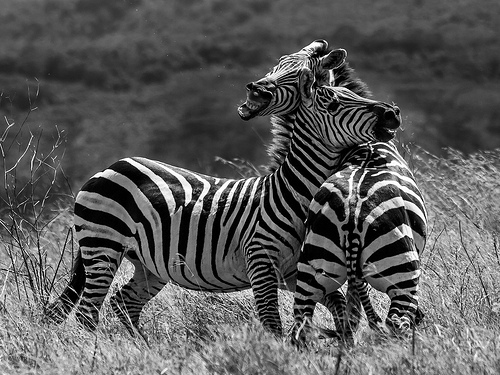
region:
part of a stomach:
[184, 210, 223, 245]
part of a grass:
[450, 229, 479, 283]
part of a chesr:
[271, 228, 288, 261]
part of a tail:
[334, 275, 364, 335]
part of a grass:
[440, 237, 471, 317]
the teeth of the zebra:
[237, 93, 264, 113]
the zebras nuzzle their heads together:
[223, 29, 413, 180]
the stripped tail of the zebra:
[323, 235, 373, 346]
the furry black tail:
[46, 258, 84, 329]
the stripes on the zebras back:
[75, 156, 297, 288]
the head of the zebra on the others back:
[299, 76, 403, 161]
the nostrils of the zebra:
[243, 77, 276, 102]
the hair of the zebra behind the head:
[328, 61, 368, 93]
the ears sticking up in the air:
[297, 32, 353, 72]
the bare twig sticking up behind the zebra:
[0, 73, 71, 327]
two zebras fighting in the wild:
[28, 31, 440, 347]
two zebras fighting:
[40, 33, 433, 350]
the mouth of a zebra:
[227, 92, 262, 119]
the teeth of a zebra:
[240, 97, 257, 112]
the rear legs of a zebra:
[75, 248, 167, 333]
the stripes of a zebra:
[145, 180, 291, 260]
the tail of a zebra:
[345, 231, 360, 334]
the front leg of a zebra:
[242, 247, 283, 332]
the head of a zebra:
[295, 70, 401, 145]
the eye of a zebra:
[326, 97, 339, 115]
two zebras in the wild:
[49, 33, 464, 345]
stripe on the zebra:
[67, 236, 122, 254]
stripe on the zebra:
[66, 195, 133, 232]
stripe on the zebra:
[85, 175, 143, 226]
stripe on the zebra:
[118, 160, 174, 277]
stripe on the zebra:
[211, 183, 219, 274]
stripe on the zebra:
[225, 179, 237, 254]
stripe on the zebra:
[373, 212, 415, 239]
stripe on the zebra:
[358, 185, 410, 210]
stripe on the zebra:
[299, 213, 341, 246]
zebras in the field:
[63, 43, 446, 345]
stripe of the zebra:
[77, 179, 140, 226]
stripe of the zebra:
[75, 237, 116, 251]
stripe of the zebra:
[71, 253, 113, 267]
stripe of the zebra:
[297, 248, 337, 270]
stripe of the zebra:
[370, 267, 419, 275]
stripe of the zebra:
[365, 240, 415, 259]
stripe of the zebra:
[384, 282, 416, 292]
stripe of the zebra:
[290, 295, 317, 304]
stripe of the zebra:
[291, 308, 312, 315]